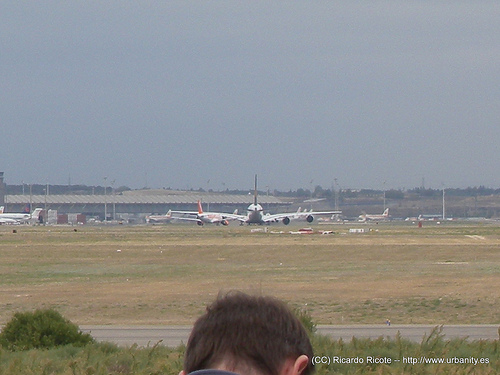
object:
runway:
[141, 223, 456, 226]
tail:
[195, 200, 206, 217]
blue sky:
[0, 0, 500, 191]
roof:
[4, 188, 294, 204]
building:
[1, 189, 296, 226]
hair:
[182, 287, 317, 373]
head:
[177, 286, 315, 374]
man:
[176, 289, 317, 374]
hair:
[184, 289, 313, 374]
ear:
[289, 353, 309, 374]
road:
[74, 322, 500, 351]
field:
[0, 219, 500, 326]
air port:
[0, 185, 500, 227]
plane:
[196, 174, 343, 227]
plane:
[356, 205, 388, 222]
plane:
[0, 205, 44, 225]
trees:
[0, 305, 98, 374]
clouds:
[0, 0, 499, 189]